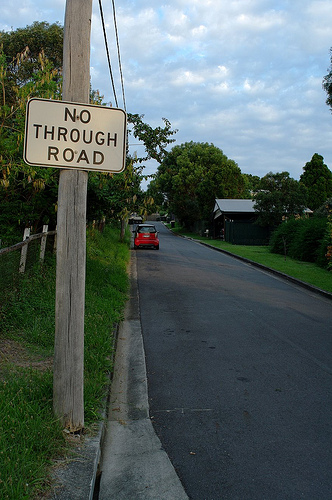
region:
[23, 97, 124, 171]
The sign is black and white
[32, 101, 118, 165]
The sign says no through road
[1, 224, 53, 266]
A wooden fence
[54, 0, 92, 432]
The pole is made of wood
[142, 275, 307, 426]
The street is dark colored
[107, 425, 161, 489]
Some lighter colored cement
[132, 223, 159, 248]
A car is parked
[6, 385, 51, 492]
Some tall green grass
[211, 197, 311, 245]
A house with a bright colored roof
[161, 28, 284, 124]
The sky is cloudy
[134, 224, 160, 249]
A small red car.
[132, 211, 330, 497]
A long straight road.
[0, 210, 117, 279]
Fence on the side of the road.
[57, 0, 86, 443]
Light pole on the side of the road.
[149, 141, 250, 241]
Large big bush on the right side of the road.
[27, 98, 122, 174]
White posted sign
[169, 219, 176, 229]
A trash can on the side of the road.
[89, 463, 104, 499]
Part of the gutter by the curb.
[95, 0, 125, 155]
Power lines going down the side of the street.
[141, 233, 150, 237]
The red car's licence plate.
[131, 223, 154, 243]
Small red car on side of road.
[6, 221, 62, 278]
Wood fence in grassy area.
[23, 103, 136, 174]
White sign attached to pole.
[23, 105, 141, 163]
Black writing on white sign.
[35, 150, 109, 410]
Wood pole near road.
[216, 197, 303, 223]
Gray roof on building.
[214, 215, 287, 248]
Green building on side of road.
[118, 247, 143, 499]
White curb on side of road.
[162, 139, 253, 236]
Large green tree next to building.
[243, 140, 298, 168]
White thin clouds in sky.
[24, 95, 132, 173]
a black and white sign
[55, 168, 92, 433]
a tall gray pole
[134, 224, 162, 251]
a small red car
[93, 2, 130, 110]
a long electrical power line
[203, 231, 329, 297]
a section of green grass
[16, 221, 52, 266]
a wooden fence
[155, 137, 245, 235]
a tall green tree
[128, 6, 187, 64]
a section of white clouds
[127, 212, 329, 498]
a paved roadway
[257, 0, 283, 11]
part of a blue sky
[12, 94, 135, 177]
a road sign on a light pole.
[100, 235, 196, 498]
a gutter on a street.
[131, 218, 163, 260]
a red car parked on a street.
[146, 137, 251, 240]
a tree filled with lots of leaves.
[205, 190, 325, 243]
a house on the side of a street.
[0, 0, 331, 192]
a cloud filled blue sky.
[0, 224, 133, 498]
grass on the side of a road.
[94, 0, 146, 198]
power lines near a road.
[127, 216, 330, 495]
a paved road near a field.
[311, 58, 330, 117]
a tree with lots of leaves.